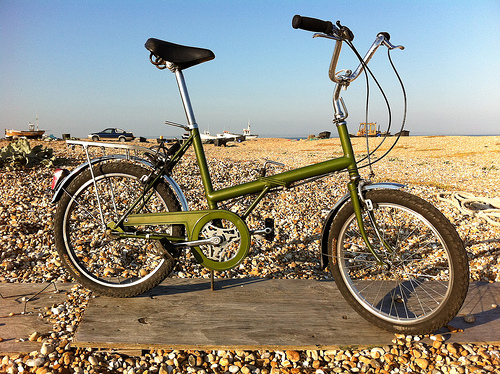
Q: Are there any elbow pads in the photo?
A: No, there are no elbow pads.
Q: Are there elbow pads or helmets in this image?
A: No, there are no elbow pads or helmets.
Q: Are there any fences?
A: No, there are no fences.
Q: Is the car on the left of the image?
A: Yes, the car is on the left of the image.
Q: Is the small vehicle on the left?
A: Yes, the car is on the left of the image.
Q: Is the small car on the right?
A: No, the car is on the left of the image.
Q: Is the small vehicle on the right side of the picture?
A: No, the car is on the left of the image.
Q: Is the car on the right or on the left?
A: The car is on the left of the image.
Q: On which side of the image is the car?
A: The car is on the left of the image.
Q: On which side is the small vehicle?
A: The car is on the left of the image.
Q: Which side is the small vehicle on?
A: The car is on the left of the image.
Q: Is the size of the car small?
A: Yes, the car is small.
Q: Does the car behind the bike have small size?
A: Yes, the car is small.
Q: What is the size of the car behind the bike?
A: The car is small.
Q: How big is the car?
A: The car is small.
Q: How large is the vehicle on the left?
A: The car is small.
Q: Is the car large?
A: No, the car is small.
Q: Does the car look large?
A: No, the car is small.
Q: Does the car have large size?
A: No, the car is small.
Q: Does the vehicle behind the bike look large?
A: No, the car is small.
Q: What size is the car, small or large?
A: The car is small.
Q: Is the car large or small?
A: The car is small.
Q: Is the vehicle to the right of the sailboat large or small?
A: The car is small.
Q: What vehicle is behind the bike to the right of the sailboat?
A: The vehicle is a car.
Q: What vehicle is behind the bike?
A: The vehicle is a car.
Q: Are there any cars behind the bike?
A: Yes, there is a car behind the bike.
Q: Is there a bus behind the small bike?
A: No, there is a car behind the bike.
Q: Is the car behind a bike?
A: Yes, the car is behind a bike.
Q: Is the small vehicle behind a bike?
A: Yes, the car is behind a bike.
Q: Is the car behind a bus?
A: No, the car is behind a bike.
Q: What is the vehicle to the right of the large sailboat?
A: The vehicle is a car.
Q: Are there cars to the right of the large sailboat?
A: Yes, there is a car to the right of the sailboat.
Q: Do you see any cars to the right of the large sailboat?
A: Yes, there is a car to the right of the sailboat.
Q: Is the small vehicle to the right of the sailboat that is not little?
A: Yes, the car is to the right of the sailboat.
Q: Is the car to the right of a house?
A: No, the car is to the right of the sailboat.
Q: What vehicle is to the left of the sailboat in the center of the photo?
A: The vehicle is a car.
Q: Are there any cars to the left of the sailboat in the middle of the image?
A: Yes, there is a car to the left of the sailboat.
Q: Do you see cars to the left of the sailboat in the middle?
A: Yes, there is a car to the left of the sailboat.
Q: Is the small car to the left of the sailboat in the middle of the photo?
A: Yes, the car is to the left of the sailboat.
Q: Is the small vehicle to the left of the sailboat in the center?
A: Yes, the car is to the left of the sailboat.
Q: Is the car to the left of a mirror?
A: No, the car is to the left of the sailboat.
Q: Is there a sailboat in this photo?
A: Yes, there is a sailboat.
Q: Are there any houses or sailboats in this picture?
A: Yes, there is a sailboat.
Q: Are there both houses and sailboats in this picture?
A: No, there is a sailboat but no houses.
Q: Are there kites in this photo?
A: No, there are no kites.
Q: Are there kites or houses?
A: No, there are no kites or houses.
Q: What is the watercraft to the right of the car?
A: The watercraft is a sailboat.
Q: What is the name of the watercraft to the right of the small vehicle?
A: The watercraft is a sailboat.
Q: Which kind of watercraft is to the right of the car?
A: The watercraft is a sailboat.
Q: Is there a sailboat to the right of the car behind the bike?
A: Yes, there is a sailboat to the right of the car.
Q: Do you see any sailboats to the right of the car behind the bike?
A: Yes, there is a sailboat to the right of the car.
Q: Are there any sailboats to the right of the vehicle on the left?
A: Yes, there is a sailboat to the right of the car.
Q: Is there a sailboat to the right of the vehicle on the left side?
A: Yes, there is a sailboat to the right of the car.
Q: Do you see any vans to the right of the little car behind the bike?
A: No, there is a sailboat to the right of the car.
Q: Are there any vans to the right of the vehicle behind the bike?
A: No, there is a sailboat to the right of the car.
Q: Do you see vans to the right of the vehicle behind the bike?
A: No, there is a sailboat to the right of the car.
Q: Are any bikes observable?
A: Yes, there is a bike.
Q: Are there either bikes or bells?
A: Yes, there is a bike.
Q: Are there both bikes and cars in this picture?
A: Yes, there are both a bike and a car.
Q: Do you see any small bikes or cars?
A: Yes, there is a small bike.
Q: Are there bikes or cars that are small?
A: Yes, the bike is small.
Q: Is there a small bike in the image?
A: Yes, there is a small bike.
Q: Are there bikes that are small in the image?
A: Yes, there is a small bike.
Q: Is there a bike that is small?
A: Yes, there is a bike that is small.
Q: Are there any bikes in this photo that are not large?
A: Yes, there is a small bike.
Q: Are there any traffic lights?
A: No, there are no traffic lights.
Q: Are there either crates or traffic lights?
A: No, there are no traffic lights or crates.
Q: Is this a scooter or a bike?
A: This is a bike.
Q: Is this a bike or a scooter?
A: This is a bike.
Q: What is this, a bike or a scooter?
A: This is a bike.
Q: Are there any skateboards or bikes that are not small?
A: No, there is a bike but it is small.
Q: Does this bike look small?
A: Yes, the bike is small.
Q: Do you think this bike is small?
A: Yes, the bike is small.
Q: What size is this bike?
A: The bike is small.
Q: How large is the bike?
A: The bike is small.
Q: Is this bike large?
A: No, the bike is small.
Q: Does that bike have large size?
A: No, the bike is small.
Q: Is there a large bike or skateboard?
A: No, there is a bike but it is small.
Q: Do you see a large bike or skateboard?
A: No, there is a bike but it is small.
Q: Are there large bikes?
A: No, there is a bike but it is small.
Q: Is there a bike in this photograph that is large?
A: No, there is a bike but it is small.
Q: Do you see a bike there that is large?
A: No, there is a bike but it is small.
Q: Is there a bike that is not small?
A: No, there is a bike but it is small.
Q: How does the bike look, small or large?
A: The bike is small.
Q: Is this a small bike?
A: Yes, this is a small bike.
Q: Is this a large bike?
A: No, this is a small bike.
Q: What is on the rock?
A: The bike is on the rock.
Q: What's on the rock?
A: The bike is on the rock.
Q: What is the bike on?
A: The bike is on the rock.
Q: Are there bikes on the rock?
A: Yes, there is a bike on the rock.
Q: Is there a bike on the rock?
A: Yes, there is a bike on the rock.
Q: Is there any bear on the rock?
A: No, there is a bike on the rock.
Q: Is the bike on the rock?
A: Yes, the bike is on the rock.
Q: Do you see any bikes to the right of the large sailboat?
A: Yes, there is a bike to the right of the sailboat.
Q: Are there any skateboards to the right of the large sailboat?
A: No, there is a bike to the right of the sailboat.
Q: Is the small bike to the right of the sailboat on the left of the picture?
A: Yes, the bike is to the right of the sailboat.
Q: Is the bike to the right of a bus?
A: No, the bike is to the right of the sailboat.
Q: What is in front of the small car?
A: The bike is in front of the car.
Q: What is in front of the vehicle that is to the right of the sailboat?
A: The bike is in front of the car.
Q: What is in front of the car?
A: The bike is in front of the car.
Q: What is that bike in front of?
A: The bike is in front of the car.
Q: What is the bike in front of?
A: The bike is in front of the car.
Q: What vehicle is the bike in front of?
A: The bike is in front of the car.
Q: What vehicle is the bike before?
A: The bike is in front of the car.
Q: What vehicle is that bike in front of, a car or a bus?
A: The bike is in front of a car.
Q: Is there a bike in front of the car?
A: Yes, there is a bike in front of the car.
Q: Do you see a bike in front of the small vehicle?
A: Yes, there is a bike in front of the car.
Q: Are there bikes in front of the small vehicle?
A: Yes, there is a bike in front of the car.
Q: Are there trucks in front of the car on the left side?
A: No, there is a bike in front of the car.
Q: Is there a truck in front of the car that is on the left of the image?
A: No, there is a bike in front of the car.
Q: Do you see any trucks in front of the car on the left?
A: No, there is a bike in front of the car.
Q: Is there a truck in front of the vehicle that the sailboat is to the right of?
A: No, there is a bike in front of the car.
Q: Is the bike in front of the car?
A: Yes, the bike is in front of the car.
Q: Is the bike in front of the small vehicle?
A: Yes, the bike is in front of the car.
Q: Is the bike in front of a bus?
A: No, the bike is in front of the car.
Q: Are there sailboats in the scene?
A: Yes, there is a sailboat.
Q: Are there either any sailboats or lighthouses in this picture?
A: Yes, there is a sailboat.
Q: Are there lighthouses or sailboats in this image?
A: Yes, there is a sailboat.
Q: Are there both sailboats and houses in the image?
A: No, there is a sailboat but no houses.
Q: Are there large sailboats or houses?
A: Yes, there is a large sailboat.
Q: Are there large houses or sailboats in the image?
A: Yes, there is a large sailboat.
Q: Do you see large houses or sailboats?
A: Yes, there is a large sailboat.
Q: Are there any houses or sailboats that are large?
A: Yes, the sailboat is large.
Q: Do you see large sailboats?
A: Yes, there is a large sailboat.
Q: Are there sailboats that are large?
A: Yes, there is a sailboat that is large.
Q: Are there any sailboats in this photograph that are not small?
A: Yes, there is a large sailboat.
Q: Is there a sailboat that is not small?
A: Yes, there is a large sailboat.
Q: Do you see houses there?
A: No, there are no houses.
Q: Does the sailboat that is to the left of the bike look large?
A: Yes, the sailboat is large.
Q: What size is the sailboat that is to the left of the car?
A: The sailboat is large.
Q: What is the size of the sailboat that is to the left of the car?
A: The sailboat is large.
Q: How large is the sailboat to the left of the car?
A: The sailboat is large.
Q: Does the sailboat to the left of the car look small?
A: No, the sailboat is large.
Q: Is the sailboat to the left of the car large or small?
A: The sailboat is large.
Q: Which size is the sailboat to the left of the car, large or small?
A: The sailboat is large.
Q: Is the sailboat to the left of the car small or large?
A: The sailboat is large.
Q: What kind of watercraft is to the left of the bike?
A: The watercraft is a sailboat.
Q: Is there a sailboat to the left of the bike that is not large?
A: Yes, there is a sailboat to the left of the bike.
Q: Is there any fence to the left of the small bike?
A: No, there is a sailboat to the left of the bike.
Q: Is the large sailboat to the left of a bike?
A: Yes, the sailboat is to the left of a bike.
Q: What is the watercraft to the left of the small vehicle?
A: The watercraft is a sailboat.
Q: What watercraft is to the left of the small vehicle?
A: The watercraft is a sailboat.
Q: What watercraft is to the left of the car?
A: The watercraft is a sailboat.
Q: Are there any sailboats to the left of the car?
A: Yes, there is a sailboat to the left of the car.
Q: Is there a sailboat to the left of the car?
A: Yes, there is a sailboat to the left of the car.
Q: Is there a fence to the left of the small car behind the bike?
A: No, there is a sailboat to the left of the car.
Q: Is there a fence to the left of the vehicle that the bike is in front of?
A: No, there is a sailboat to the left of the car.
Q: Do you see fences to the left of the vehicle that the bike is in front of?
A: No, there is a sailboat to the left of the car.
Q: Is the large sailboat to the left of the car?
A: Yes, the sailboat is to the left of the car.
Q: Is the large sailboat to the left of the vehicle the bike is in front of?
A: Yes, the sailboat is to the left of the car.